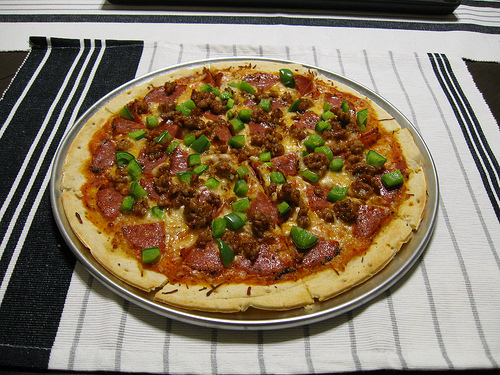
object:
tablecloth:
[0, 1, 500, 374]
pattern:
[158, 330, 223, 374]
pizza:
[58, 58, 430, 315]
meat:
[130, 197, 151, 218]